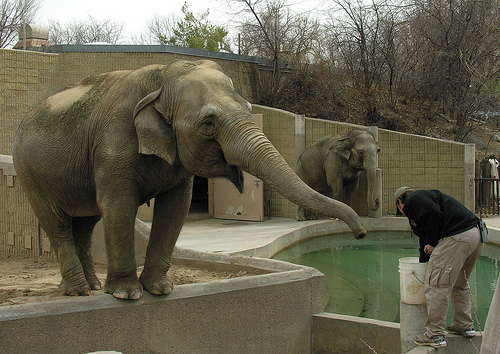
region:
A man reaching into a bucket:
[396, 183, 483, 348]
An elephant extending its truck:
[12, 55, 366, 295]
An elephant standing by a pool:
[298, 127, 382, 221]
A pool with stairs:
[261, 222, 498, 337]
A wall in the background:
[0, 48, 475, 225]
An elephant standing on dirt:
[0, 60, 366, 302]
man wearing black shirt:
[382, 179, 482, 346]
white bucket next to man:
[393, 255, 429, 307]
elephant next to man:
[8, 46, 364, 290]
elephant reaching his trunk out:
[12, 64, 362, 291]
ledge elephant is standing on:
[5, 270, 314, 347]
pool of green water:
[283, 217, 495, 329]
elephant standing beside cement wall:
[299, 118, 379, 217]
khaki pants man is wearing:
[428, 227, 484, 329]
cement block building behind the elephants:
[3, 38, 475, 217]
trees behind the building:
[10, 9, 492, 130]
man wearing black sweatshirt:
[375, 168, 487, 338]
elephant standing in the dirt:
[18, 43, 359, 310]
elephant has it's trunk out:
[20, 40, 350, 289]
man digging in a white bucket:
[380, 157, 495, 334]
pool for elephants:
[302, 195, 479, 335]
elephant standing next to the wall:
[282, 115, 383, 223]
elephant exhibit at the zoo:
[15, 30, 479, 340]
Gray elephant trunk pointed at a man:
[236, 125, 366, 239]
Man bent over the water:
[393, 182, 488, 342]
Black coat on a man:
[410, 190, 480, 262]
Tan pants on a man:
[427, 223, 482, 328]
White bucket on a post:
[402, 255, 426, 300]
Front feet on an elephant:
[107, 280, 175, 298]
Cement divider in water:
[302, 298, 404, 352]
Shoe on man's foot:
[413, 334, 446, 349]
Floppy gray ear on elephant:
[130, 90, 177, 166]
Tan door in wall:
[210, 110, 266, 218]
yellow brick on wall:
[449, 143, 464, 152]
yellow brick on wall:
[436, 144, 451, 154]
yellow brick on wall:
[424, 143, 439, 153]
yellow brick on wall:
[388, 131, 399, 140]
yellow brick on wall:
[386, 145, 399, 154]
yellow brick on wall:
[388, 157, 398, 165]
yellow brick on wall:
[381, 186, 391, 195]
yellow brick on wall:
[326, 125, 338, 133]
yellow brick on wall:
[27, 68, 44, 76]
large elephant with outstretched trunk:
[10, 54, 373, 309]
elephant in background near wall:
[291, 124, 381, 220]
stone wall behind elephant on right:
[247, 97, 480, 233]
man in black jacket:
[382, 180, 498, 347]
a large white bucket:
[398, 255, 427, 303]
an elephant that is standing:
[18, 48, 385, 310]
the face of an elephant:
[127, 52, 279, 209]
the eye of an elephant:
[178, 93, 233, 141]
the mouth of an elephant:
[208, 132, 259, 202]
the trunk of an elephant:
[244, 145, 381, 256]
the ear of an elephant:
[121, 83, 192, 171]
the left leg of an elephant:
[145, 186, 189, 300]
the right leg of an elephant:
[84, 172, 141, 304]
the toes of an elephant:
[100, 275, 148, 312]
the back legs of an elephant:
[21, 222, 111, 302]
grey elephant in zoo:
[15, 58, 381, 314]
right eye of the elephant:
[192, 101, 217, 118]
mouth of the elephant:
[211, 145, 242, 185]